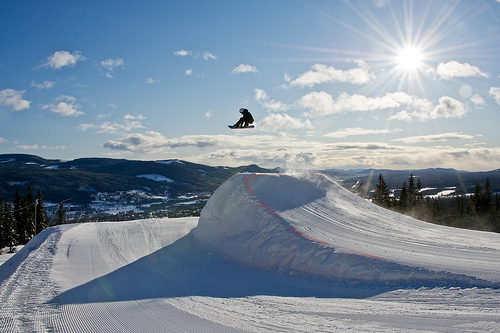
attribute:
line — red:
[237, 167, 308, 237]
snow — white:
[96, 308, 269, 323]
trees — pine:
[0, 209, 41, 246]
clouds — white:
[299, 63, 390, 114]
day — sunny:
[51, 0, 487, 175]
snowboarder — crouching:
[197, 93, 263, 135]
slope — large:
[285, 172, 396, 243]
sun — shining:
[399, 52, 430, 85]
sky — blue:
[254, 8, 452, 124]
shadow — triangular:
[85, 254, 294, 306]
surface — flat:
[197, 256, 299, 287]